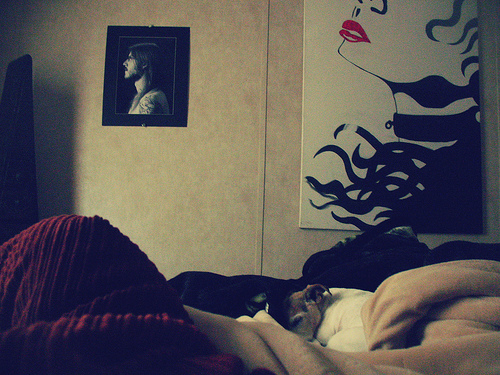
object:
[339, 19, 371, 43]
lips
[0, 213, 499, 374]
bed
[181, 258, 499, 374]
blanket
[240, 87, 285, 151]
ground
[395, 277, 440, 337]
color beige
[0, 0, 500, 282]
wall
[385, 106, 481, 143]
choker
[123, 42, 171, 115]
man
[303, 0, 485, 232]
woman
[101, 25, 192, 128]
frame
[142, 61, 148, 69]
ear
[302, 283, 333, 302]
ear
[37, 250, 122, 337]
red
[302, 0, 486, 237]
woman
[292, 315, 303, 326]
eye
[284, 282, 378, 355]
dog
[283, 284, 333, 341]
head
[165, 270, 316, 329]
dog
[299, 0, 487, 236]
painting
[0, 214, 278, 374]
blanket